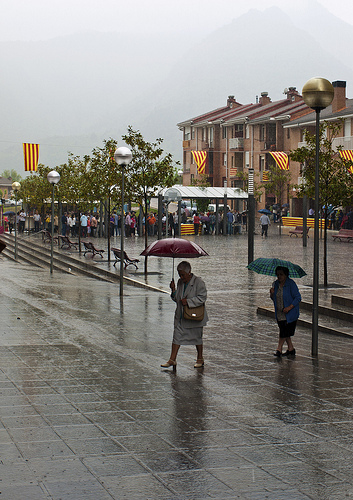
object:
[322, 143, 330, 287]
tree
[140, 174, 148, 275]
tree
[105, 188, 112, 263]
tree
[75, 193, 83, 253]
tree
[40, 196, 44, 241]
tree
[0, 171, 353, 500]
park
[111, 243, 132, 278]
bench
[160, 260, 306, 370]
two women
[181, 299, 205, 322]
purse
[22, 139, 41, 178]
flag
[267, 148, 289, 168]
flag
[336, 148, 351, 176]
flag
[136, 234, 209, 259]
umbrella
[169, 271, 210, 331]
jacket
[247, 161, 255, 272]
pole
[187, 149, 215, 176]
flag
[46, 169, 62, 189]
lights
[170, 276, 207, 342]
dress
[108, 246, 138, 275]
benches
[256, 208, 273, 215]
umbrella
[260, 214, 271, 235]
woman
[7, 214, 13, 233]
woman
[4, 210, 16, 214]
umbrella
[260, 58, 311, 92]
ground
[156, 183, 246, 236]
structure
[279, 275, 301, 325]
plastic chair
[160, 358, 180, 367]
shoes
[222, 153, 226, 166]
window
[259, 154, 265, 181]
window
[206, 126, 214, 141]
window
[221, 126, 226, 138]
window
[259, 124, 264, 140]
window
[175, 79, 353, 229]
building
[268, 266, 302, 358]
woman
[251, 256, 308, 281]
umbrella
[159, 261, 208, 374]
woman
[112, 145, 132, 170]
light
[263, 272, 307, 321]
jacket